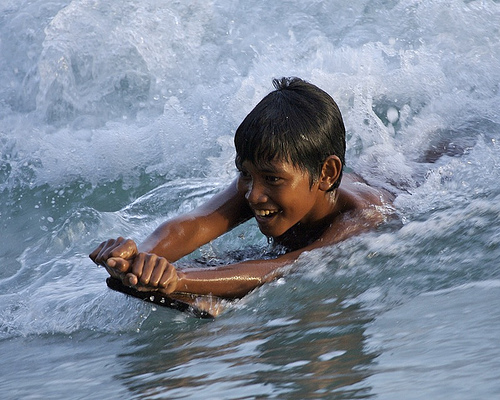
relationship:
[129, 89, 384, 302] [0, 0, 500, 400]
boy in ocean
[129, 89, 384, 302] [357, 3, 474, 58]
boy in ocean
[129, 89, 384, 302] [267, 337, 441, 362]
boy riding wave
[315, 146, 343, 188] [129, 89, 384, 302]
ear of boy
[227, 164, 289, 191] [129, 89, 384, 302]
eyes of boy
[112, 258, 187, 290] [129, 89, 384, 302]
fingers of boy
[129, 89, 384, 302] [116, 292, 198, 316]
boy on surfboard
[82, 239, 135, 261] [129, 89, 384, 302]
hands of boy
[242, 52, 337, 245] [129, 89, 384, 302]
head of boy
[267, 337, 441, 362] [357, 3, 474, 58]
wave in ocean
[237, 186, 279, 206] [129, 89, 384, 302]
nose of boy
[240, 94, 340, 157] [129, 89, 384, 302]
hair of boy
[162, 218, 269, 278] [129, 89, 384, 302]
arms of boy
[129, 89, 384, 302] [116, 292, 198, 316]
boy riding surfboard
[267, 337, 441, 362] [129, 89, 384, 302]
wave behind boy